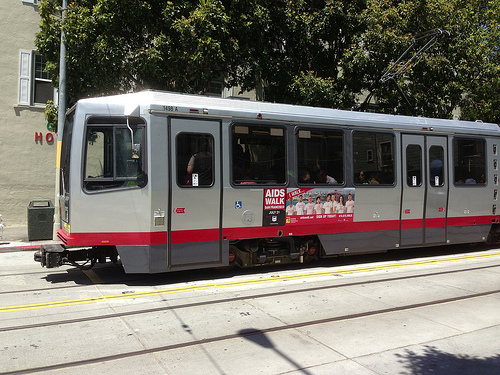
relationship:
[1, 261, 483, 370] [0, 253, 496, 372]
tracks on concrete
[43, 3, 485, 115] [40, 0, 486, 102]
leaves on tree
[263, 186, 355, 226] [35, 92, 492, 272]
poster on train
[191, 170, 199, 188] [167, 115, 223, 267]
sign on door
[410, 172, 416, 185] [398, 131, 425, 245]
sign on door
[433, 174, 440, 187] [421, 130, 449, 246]
sign on door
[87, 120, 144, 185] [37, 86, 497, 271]
window on streetcar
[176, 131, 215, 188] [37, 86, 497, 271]
window on streetcar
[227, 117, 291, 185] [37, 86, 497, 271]
window on streetcar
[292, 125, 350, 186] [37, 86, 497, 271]
window on streetcar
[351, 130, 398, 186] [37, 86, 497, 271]
window on streetcar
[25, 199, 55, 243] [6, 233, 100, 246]
trash bin on sidewalk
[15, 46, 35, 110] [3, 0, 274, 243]
shutter on building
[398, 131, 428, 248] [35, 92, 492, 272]
door on train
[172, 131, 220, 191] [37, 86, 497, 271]
window on streetcar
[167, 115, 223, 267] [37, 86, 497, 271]
door on streetcar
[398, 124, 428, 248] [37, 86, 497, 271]
door on streetcar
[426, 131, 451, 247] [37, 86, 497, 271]
door on streetcar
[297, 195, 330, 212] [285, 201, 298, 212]
people in t-shirts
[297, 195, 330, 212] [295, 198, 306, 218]
people in t-shirts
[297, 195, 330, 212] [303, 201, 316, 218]
people in t-shirts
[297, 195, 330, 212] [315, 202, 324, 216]
people in t-shirts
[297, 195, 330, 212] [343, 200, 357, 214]
people in t-shirts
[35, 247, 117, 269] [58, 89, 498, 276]
handleconnector post on trolley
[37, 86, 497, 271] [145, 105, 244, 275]
streetcar has door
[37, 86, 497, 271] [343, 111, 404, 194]
streetcar has window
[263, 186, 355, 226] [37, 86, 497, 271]
poster on streetcar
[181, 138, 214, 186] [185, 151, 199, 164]
person wearing shirt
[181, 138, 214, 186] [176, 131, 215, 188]
person in window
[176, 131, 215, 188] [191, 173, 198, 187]
window has sign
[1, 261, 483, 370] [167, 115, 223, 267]
tracks has door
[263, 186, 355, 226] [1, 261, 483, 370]
poster on tracks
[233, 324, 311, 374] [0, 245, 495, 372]
shadow on pavement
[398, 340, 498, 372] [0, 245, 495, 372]
shadow on pavement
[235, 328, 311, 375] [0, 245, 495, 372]
shadow on pavement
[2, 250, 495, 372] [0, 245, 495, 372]
shadow on pavement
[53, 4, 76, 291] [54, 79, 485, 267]
light pole behind trolly